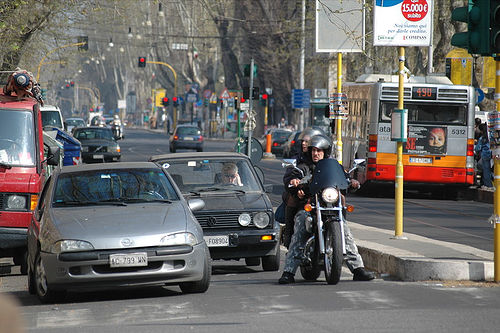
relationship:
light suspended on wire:
[138, 54, 147, 69] [4, 26, 239, 56]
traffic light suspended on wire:
[69, 80, 74, 87] [4, 26, 239, 56]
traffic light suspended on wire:
[67, 84, 71, 88] [4, 26, 239, 56]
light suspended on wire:
[160, 97, 165, 106] [160, 85, 184, 147]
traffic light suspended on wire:
[168, 92, 178, 109] [164, 96, 187, 150]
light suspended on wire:
[153, 2, 164, 19] [104, 0, 181, 20]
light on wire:
[138, 54, 147, 69] [46, 23, 310, 57]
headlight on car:
[237, 212, 251, 227] [146, 151, 281, 269]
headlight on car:
[254, 209, 270, 228] [146, 151, 281, 269]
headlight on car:
[159, 230, 199, 245] [27, 162, 213, 302]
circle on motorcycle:
[321, 188, 338, 203] [288, 161, 389, 263]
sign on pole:
[377, 8, 435, 45] [391, 65, 407, 106]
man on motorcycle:
[276, 135, 373, 283] [275, 156, 367, 285]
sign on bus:
[392, 124, 446, 155] [315, 67, 473, 197]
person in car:
[217, 161, 242, 188] [172, 148, 277, 265]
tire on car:
[32, 244, 57, 300] [27, 162, 213, 302]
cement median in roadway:
[343, 218, 498, 279] [6, 119, 498, 331]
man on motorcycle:
[276, 135, 373, 283] [290, 167, 381, 296]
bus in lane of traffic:
[330, 73, 476, 201] [0, 98, 499, 301]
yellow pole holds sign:
[390, 46, 408, 238] [370, 3, 437, 48]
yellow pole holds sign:
[330, 50, 348, 167] [311, 3, 366, 57]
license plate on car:
[107, 246, 150, 269] [22, 155, 212, 290]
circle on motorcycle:
[321, 188, 338, 203] [282, 152, 363, 282]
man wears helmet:
[276, 130, 374, 283] [305, 132, 332, 155]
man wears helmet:
[276, 130, 374, 283] [296, 124, 328, 135]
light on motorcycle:
[342, 202, 357, 217] [265, 136, 368, 288]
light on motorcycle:
[300, 193, 316, 215] [265, 136, 368, 288]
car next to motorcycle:
[27, 162, 213, 302] [275, 156, 367, 285]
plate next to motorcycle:
[198, 217, 246, 252] [274, 139, 385, 273]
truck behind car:
[0, 71, 57, 243] [27, 162, 213, 302]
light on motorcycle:
[300, 203, 312, 212] [275, 156, 367, 285]